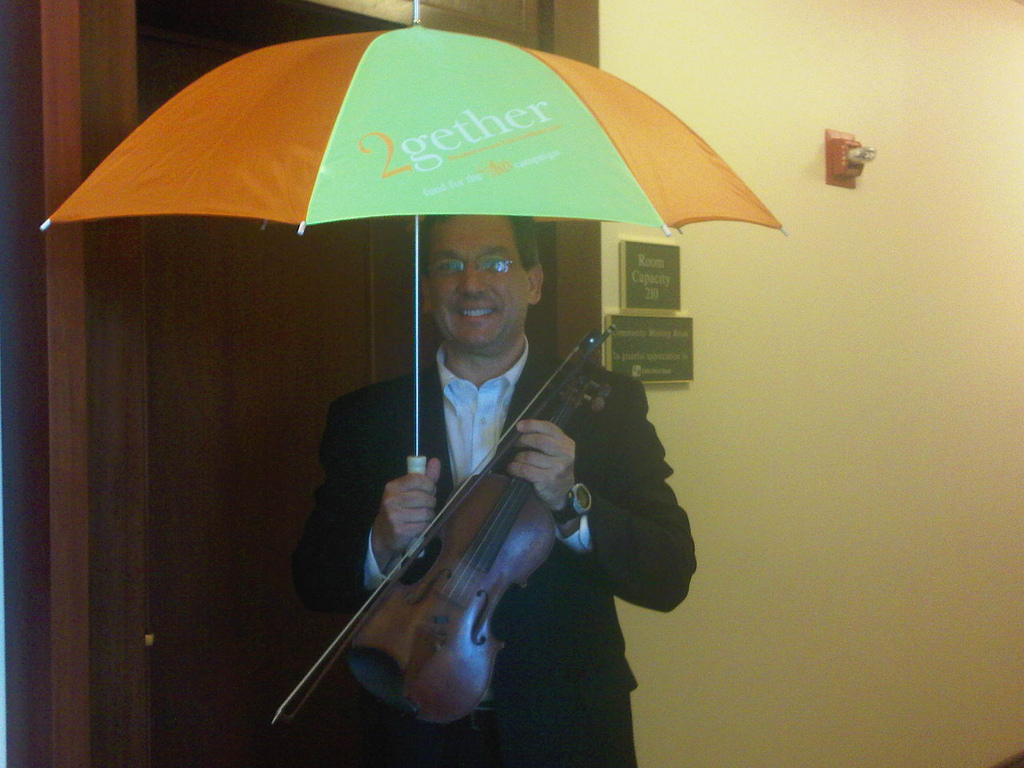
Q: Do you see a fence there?
A: No, there are no fences.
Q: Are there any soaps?
A: No, there are no soaps.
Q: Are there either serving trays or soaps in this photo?
A: No, there are no soaps or serving trays.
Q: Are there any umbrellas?
A: Yes, there is an umbrella.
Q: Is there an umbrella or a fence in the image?
A: Yes, there is an umbrella.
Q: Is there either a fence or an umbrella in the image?
A: Yes, there is an umbrella.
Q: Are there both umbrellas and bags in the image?
A: No, there is an umbrella but no bags.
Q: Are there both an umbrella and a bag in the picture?
A: No, there is an umbrella but no bags.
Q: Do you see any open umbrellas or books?
A: Yes, there is an open umbrella.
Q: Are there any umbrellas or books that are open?
A: Yes, the umbrella is open.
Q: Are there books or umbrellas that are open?
A: Yes, the umbrella is open.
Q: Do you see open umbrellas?
A: Yes, there is an open umbrella.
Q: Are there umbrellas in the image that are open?
A: Yes, there is an umbrella that is open.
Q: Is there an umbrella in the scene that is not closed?
A: Yes, there is a open umbrella.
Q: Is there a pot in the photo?
A: No, there are no pots.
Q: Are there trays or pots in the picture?
A: No, there are no pots or trays.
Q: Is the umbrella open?
A: Yes, the umbrella is open.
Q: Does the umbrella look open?
A: Yes, the umbrella is open.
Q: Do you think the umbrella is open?
A: Yes, the umbrella is open.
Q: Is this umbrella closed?
A: No, the umbrella is open.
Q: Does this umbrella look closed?
A: No, the umbrella is open.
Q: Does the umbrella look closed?
A: No, the umbrella is open.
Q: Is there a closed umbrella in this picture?
A: No, there is an umbrella but it is open.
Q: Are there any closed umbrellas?
A: No, there is an umbrella but it is open.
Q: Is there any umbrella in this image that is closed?
A: No, there is an umbrella but it is open.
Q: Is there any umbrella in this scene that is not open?
A: No, there is an umbrella but it is open.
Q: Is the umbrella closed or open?
A: The umbrella is open.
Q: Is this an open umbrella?
A: Yes, this is an open umbrella.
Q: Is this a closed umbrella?
A: No, this is an open umbrella.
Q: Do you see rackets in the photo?
A: No, there are no rackets.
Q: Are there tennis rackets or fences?
A: No, there are no tennis rackets or fences.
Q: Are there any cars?
A: No, there are no cars.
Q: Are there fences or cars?
A: No, there are no cars or fences.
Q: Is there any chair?
A: No, there are no chairs.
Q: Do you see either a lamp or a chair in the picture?
A: No, there are no chairs or lamps.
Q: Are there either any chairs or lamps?
A: No, there are no chairs or lamps.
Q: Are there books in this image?
A: No, there are no books.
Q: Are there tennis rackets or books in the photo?
A: No, there are no books or tennis rackets.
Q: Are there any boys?
A: No, there are no boys.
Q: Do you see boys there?
A: No, there are no boys.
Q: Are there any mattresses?
A: No, there are no mattresses.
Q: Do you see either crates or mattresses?
A: No, there are no mattresses or crates.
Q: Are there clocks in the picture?
A: Yes, there is a clock.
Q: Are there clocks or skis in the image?
A: Yes, there is a clock.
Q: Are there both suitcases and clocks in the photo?
A: No, there is a clock but no suitcases.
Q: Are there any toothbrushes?
A: No, there are no toothbrushes.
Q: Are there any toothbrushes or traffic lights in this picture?
A: No, there are no toothbrushes or traffic lights.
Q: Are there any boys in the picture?
A: No, there are no boys.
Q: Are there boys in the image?
A: No, there are no boys.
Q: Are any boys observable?
A: No, there are no boys.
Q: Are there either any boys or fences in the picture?
A: No, there are no boys or fences.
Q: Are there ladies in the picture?
A: No, there are no ladies.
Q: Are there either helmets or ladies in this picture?
A: No, there are no ladies or helmets.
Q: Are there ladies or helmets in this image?
A: No, there are no ladies or helmets.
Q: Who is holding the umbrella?
A: The man is holding the umbrella.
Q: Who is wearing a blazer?
A: The man is wearing a blazer.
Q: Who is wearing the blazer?
A: The man is wearing a blazer.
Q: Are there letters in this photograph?
A: Yes, there are letters.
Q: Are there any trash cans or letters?
A: Yes, there are letters.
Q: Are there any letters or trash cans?
A: Yes, there are letters.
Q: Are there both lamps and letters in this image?
A: No, there are letters but no lamps.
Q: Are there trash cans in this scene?
A: No, there are no trash cans.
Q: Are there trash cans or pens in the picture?
A: No, there are no trash cans or pens.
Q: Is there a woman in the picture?
A: No, there are no women.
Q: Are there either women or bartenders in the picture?
A: No, there are no women or bartenders.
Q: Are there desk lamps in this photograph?
A: No, there are no desk lamps.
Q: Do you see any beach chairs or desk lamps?
A: No, there are no desk lamps or beach chairs.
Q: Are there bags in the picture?
A: No, there are no bags.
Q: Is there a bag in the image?
A: No, there are no bags.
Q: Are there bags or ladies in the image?
A: No, there are no bags or ladies.